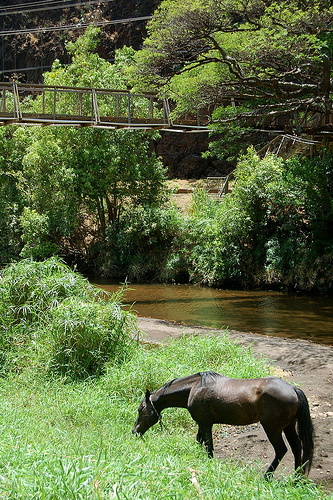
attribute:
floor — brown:
[161, 177, 238, 218]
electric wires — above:
[2, 0, 162, 76]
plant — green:
[0, 383, 213, 499]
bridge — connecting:
[41, 66, 256, 143]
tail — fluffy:
[278, 379, 320, 482]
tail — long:
[291, 385, 314, 478]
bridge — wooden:
[3, 83, 184, 131]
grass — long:
[1, 342, 331, 498]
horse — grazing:
[112, 365, 317, 484]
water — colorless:
[79, 276, 331, 348]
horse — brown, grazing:
[129, 366, 315, 488]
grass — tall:
[0, 356, 176, 498]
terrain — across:
[2, 177, 332, 230]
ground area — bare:
[136, 317, 331, 483]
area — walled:
[140, 138, 215, 190]